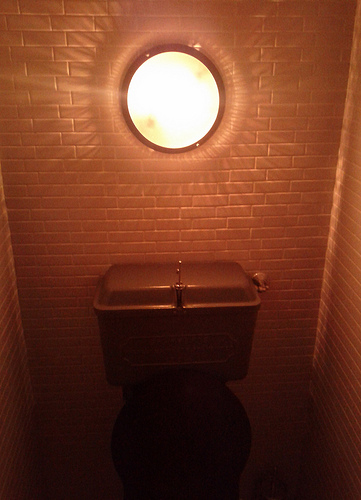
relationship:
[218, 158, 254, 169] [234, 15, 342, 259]
brick of wall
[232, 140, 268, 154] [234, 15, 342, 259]
brick of wall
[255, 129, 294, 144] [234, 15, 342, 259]
brick of wall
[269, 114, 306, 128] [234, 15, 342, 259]
brick of wall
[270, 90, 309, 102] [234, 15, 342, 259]
brick of wall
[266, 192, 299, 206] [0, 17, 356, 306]
brick of a wall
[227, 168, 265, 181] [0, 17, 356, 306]
brick of a wall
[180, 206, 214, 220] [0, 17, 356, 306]
brick of a wall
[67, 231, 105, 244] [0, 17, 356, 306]
brick of a wall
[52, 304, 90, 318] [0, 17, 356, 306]
brick of a wall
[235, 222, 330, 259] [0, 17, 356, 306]
bricks of a wall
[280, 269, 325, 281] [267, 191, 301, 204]
brick of a wall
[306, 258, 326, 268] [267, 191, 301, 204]
brick of a wall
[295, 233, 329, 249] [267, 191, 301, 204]
brick of a wall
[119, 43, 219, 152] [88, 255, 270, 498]
light behind toilet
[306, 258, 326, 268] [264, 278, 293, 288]
brick next to brick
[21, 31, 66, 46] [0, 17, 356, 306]
brick on wall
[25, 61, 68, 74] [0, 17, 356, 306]
brick on wall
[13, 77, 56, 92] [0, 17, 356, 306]
brick on wall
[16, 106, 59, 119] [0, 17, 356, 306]
brick on wall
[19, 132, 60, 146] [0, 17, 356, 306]
brick on wall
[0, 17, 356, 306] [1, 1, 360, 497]
wall in bathroom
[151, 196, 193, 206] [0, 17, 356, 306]
white brick on wall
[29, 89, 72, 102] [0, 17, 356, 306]
brick on wall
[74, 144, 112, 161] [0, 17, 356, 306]
brick on wall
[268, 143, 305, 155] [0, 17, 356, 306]
brick on wall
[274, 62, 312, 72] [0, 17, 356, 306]
brick on wall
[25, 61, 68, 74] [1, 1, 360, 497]
brick in bathroom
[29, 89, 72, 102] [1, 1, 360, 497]
brick in bathroom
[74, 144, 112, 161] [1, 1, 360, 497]
brick in bathroom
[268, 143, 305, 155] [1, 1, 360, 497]
brick in bathroom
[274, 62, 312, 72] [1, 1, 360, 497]
brick in bathroom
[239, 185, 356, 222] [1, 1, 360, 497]
wall in bathroom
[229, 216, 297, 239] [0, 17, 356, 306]
bricks on wall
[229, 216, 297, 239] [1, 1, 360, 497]
bricks in bathroom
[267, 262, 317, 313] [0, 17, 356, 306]
bricks on wall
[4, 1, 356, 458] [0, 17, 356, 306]
white bricks on wall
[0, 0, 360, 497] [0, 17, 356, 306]
bricks on wall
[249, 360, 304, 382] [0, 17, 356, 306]
bricks on wall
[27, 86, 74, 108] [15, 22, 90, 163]
bricks on wall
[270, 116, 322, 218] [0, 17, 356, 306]
bricks on wall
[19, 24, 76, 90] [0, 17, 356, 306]
bricks on wall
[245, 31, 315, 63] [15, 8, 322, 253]
bricks on wall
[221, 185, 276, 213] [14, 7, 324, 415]
bricks on wall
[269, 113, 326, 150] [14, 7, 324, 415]
bricks on wall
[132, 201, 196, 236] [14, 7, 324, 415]
bricks on wall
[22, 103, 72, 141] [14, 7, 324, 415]
bricks on wall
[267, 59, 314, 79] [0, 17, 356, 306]
bricks on wall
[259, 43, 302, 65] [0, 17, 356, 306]
bricks on wall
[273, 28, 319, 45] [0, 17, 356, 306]
bricks on wall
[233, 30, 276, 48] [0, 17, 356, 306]
bricks on wall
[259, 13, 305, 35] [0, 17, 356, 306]
bricks on wall